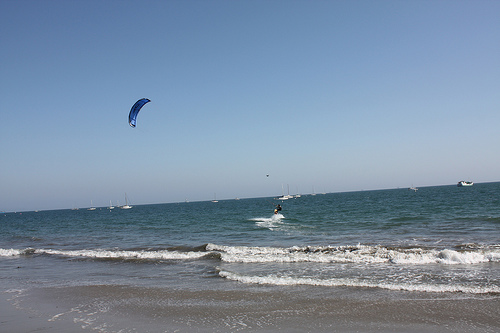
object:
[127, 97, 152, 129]
sail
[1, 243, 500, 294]
waves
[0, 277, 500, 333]
shore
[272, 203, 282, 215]
person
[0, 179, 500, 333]
ocean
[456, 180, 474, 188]
boat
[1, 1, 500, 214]
air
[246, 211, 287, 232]
wave